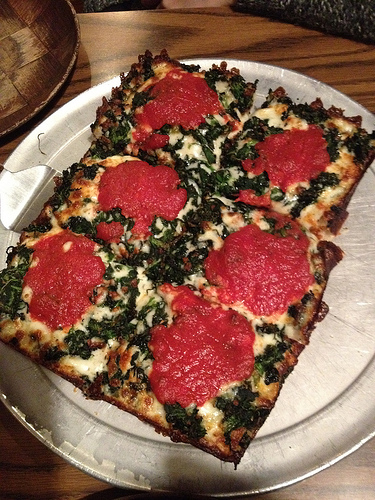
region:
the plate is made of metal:
[2, 60, 371, 492]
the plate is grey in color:
[2, 61, 373, 492]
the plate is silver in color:
[0, 60, 372, 488]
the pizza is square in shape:
[5, 52, 364, 459]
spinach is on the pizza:
[187, 168, 224, 195]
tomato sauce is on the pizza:
[214, 230, 314, 309]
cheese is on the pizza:
[199, 228, 222, 247]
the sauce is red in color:
[217, 232, 306, 309]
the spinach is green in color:
[150, 263, 181, 284]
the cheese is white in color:
[65, 352, 115, 377]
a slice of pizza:
[109, 45, 226, 176]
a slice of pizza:
[240, 87, 368, 212]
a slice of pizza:
[74, 150, 193, 266]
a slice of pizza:
[186, 197, 321, 315]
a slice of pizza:
[15, 234, 123, 372]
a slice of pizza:
[133, 301, 251, 425]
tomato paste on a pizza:
[127, 70, 227, 142]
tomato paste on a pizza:
[245, 129, 336, 191]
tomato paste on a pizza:
[96, 147, 187, 252]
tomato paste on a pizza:
[190, 221, 320, 303]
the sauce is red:
[19, 219, 99, 325]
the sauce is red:
[127, 278, 237, 400]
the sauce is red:
[202, 217, 314, 328]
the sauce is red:
[86, 168, 196, 251]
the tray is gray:
[273, 345, 351, 468]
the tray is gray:
[31, 393, 212, 498]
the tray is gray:
[242, 378, 356, 488]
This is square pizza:
[60, 221, 305, 461]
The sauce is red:
[156, 309, 247, 421]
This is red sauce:
[175, 320, 290, 451]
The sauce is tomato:
[130, 295, 201, 393]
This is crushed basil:
[157, 368, 232, 431]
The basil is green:
[190, 412, 201, 427]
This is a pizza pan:
[91, 435, 188, 480]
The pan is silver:
[117, 413, 142, 453]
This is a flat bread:
[147, 365, 247, 453]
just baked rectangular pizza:
[4, 44, 374, 460]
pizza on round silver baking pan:
[14, 45, 371, 490]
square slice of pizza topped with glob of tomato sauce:
[97, 281, 306, 472]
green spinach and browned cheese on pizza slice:
[109, 279, 284, 467]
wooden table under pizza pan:
[4, 4, 373, 489]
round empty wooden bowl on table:
[4, 0, 84, 134]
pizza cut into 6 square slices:
[2, 42, 373, 464]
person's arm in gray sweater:
[231, 0, 372, 59]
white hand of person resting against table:
[156, 0, 233, 16]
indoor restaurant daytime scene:
[4, 6, 366, 484]